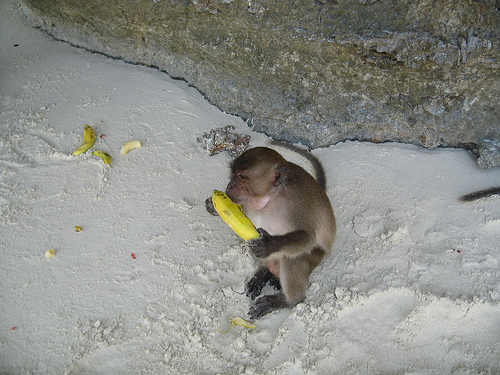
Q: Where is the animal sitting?
A: On the beach.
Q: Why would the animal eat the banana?
A: Because he is hungry.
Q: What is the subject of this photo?
A: Monkey.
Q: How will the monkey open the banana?
A: With his hands.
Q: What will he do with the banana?
A: Eat it.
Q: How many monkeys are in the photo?
A: 1.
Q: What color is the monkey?
A: Brown.